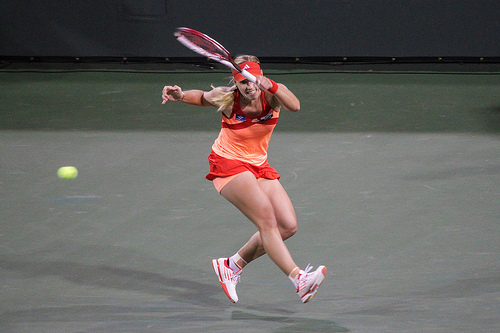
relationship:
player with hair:
[160, 54, 327, 304] [209, 77, 239, 117]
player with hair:
[160, 54, 327, 304] [227, 53, 264, 65]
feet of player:
[207, 251, 327, 311] [160, 54, 327, 304]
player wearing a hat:
[160, 54, 327, 304] [228, 63, 260, 80]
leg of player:
[209, 161, 327, 303] [160, 48, 324, 305]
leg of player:
[210, 166, 298, 304] [160, 48, 324, 305]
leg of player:
[239, 176, 303, 272] [160, 54, 327, 304]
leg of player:
[209, 170, 301, 281] [160, 54, 327, 304]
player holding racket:
[160, 54, 327, 304] [171, 22, 261, 84]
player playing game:
[160, 54, 327, 304] [4, 2, 497, 331]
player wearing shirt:
[160, 54, 327, 304] [210, 89, 281, 168]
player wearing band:
[160, 54, 327, 304] [265, 77, 279, 95]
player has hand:
[160, 48, 324, 305] [254, 73, 274, 93]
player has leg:
[160, 54, 327, 304] [212, 172, 328, 304]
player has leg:
[160, 54, 327, 304] [208, 178, 300, 306]